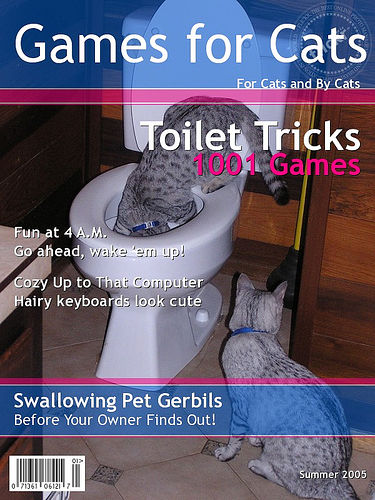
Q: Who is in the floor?
A: A cat.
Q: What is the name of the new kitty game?
A: Toilet tricks.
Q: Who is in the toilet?
A: A cat.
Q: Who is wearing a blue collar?
A: A cat.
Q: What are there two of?
A: Cats.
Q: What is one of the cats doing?
A: Drinking out of toilet.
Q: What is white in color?
A: Toilet.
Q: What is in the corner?
A: Plunger.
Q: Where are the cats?
A: In bathroom.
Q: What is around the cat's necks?
A: Collars.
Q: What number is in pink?
A: 1001.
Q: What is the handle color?
A: Yellow.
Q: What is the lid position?
A: Up.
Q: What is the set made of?
A: Wicker.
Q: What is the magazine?
A: Games for cats.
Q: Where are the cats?
A: In the bathroom.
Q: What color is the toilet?
A: White.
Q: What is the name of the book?
A: Games for cats.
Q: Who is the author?
A: Cats.